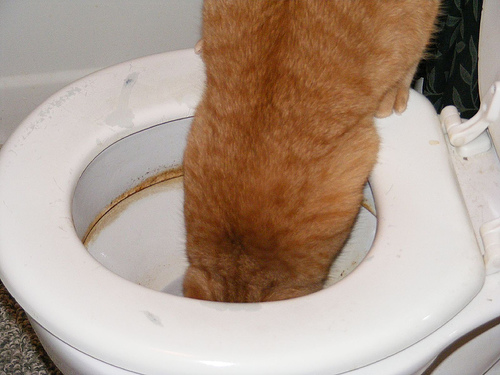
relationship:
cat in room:
[177, 2, 447, 305] [0, 0, 500, 375]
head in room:
[180, 266, 325, 307] [0, 0, 500, 375]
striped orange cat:
[297, 12, 392, 122] [177, 2, 447, 305]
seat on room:
[4, 41, 477, 373] [0, 0, 500, 375]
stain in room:
[80, 160, 193, 251] [0, 0, 500, 375]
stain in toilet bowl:
[80, 160, 193, 251] [71, 107, 384, 305]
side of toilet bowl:
[0, 4, 204, 44] [71, 107, 384, 305]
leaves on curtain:
[454, 61, 474, 90] [416, 1, 484, 120]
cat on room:
[177, 2, 447, 305] [0, 0, 500, 375]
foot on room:
[373, 78, 415, 124] [0, 0, 500, 375]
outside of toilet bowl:
[423, 320, 498, 374] [71, 107, 384, 305]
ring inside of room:
[80, 160, 193, 251] [0, 0, 500, 375]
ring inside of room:
[361, 201, 373, 220] [0, 0, 500, 375]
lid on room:
[476, 1, 500, 160] [0, 0, 500, 375]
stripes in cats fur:
[212, 11, 255, 120] [177, 2, 447, 305]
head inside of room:
[180, 266, 325, 307] [0, 0, 500, 375]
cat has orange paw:
[177, 2, 447, 305] [197, 30, 212, 63]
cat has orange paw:
[177, 2, 447, 305] [373, 78, 415, 124]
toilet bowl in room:
[71, 107, 384, 305] [0, 0, 500, 375]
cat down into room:
[177, 2, 447, 305] [0, 0, 500, 375]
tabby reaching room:
[177, 2, 447, 305] [0, 0, 500, 375]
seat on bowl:
[4, 41, 477, 373] [71, 107, 384, 305]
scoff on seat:
[109, 72, 144, 133] [4, 41, 477, 373]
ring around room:
[361, 201, 373, 220] [0, 0, 500, 375]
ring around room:
[80, 160, 193, 251] [0, 0, 500, 375]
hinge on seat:
[440, 78, 499, 157] [4, 41, 477, 373]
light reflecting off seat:
[187, 352, 241, 371] [4, 41, 477, 373]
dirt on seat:
[418, 135, 444, 152] [4, 41, 477, 373]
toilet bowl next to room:
[71, 107, 384, 305] [0, 0, 500, 375]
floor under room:
[0, 329, 42, 375] [0, 0, 500, 375]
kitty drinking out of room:
[177, 2, 447, 305] [0, 0, 500, 375]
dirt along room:
[418, 135, 444, 152] [0, 0, 500, 375]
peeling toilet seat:
[109, 72, 144, 133] [4, 41, 477, 373]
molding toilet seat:
[0, 61, 107, 155] [4, 41, 477, 373]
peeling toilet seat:
[195, 298, 263, 311] [4, 41, 477, 373]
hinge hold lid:
[440, 78, 499, 157] [476, 1, 500, 160]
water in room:
[155, 271, 186, 297] [0, 0, 500, 375]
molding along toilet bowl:
[0, 62, 114, 143] [71, 107, 384, 305]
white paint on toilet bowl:
[51, 17, 119, 54] [71, 107, 384, 305]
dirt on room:
[418, 135, 444, 152] [0, 0, 500, 375]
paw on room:
[197, 30, 212, 63] [0, 0, 500, 375]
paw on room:
[373, 78, 415, 124] [0, 0, 500, 375]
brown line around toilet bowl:
[80, 160, 193, 251] [71, 107, 384, 305]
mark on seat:
[52, 203, 75, 241] [4, 41, 477, 373]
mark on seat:
[358, 252, 378, 266] [4, 41, 477, 373]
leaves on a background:
[454, 61, 474, 90] [416, 1, 484, 120]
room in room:
[0, 0, 500, 375] [10, 5, 410, 368]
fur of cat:
[177, 2, 447, 305] [176, 15, 395, 298]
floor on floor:
[0, 329, 42, 375] [0, 329, 26, 367]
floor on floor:
[0, 329, 42, 375] [0, 329, 42, 375]